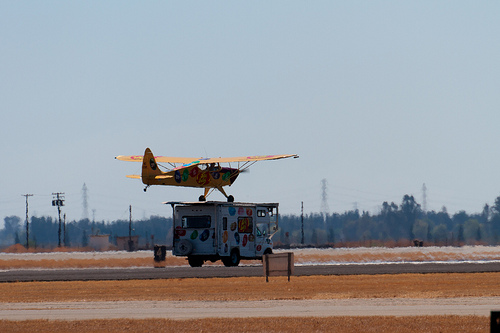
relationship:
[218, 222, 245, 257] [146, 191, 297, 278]
stickers on truck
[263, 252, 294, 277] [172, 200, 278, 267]
sign next to truck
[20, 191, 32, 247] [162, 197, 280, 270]
pole behind truck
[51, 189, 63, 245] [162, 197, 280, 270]
pole behind truck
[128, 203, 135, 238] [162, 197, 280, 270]
pole behind truck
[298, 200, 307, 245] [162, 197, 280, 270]
pole behind truck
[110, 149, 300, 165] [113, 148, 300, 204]
wings of plane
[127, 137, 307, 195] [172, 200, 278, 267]
plane on top of truck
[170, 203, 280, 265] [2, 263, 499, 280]
truck on road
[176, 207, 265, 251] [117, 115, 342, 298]
drawings all over truck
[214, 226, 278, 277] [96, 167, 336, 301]
wheel of truck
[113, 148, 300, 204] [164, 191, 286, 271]
plane above truck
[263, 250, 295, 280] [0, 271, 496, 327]
sign in ground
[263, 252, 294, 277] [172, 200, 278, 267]
sign front of truck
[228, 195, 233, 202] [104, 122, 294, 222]
wheel on glider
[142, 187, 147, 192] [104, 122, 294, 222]
wheel on glider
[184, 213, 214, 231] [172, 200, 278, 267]
window on truck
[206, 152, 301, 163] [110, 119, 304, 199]
wings on plane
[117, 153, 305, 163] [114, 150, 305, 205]
wings on plane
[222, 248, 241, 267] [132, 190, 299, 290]
wheel on train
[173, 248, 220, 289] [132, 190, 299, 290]
wheel on train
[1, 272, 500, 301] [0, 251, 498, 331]
grass on ground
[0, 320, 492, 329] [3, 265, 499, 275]
grass next to runway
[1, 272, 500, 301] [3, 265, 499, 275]
grass next to runway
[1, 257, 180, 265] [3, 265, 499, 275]
grass next to runway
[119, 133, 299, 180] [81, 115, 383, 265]
wings on plane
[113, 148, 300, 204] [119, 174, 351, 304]
plane on truck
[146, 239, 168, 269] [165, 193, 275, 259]
garbage can next to truck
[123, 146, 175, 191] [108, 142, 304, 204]
tail on plane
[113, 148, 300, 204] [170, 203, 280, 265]
plane on top of truck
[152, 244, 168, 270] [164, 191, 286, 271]
garbage can behind truck